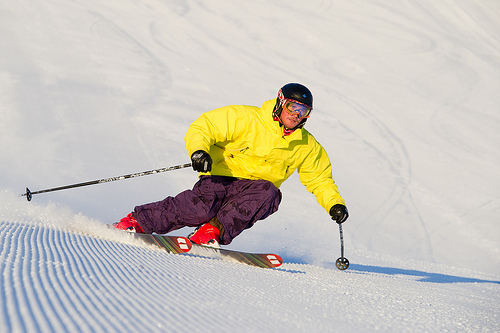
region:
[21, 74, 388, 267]
A man skiing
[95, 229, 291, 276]
A pair of skis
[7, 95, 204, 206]
A ski pole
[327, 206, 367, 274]
A ski pole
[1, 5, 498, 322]
The ground covered in snow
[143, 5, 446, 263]
ski tracks in the snow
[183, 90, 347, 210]
Yellow jacket on the skier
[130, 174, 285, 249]
purple pants on the skier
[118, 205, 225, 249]
red shoes on the skier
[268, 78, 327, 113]
black helmet on the skier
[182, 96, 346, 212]
skier in yellow jacket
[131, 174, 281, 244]
skier in purple pants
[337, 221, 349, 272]
ski pole in left hand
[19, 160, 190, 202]
ski pole in right hand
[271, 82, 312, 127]
skier wearing black helmet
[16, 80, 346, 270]
skier is leaning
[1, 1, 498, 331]
skier is on slope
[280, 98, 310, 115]
goggles are under helmet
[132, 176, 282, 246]
purple pants are loose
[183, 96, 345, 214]
yellow jacket is fastened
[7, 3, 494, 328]
snow covered hill side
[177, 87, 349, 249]
bright yellow ski jacket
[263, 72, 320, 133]
shiny black safety helmet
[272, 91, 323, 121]
red safety ski goggles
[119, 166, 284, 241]
baggy purple ski pants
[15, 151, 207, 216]
outstretched black ski pole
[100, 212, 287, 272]
pair of red and green skis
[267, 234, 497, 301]
shadow of skier in snow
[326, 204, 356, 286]
ski pole in left hand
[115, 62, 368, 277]
downhill skier making a turn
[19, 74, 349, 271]
man skiing in the snow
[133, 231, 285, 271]
silver skiis with red and white tips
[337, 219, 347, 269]
left skii pole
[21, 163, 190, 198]
right skii pole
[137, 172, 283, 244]
purple pants on skiier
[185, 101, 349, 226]
yellow jacket on skiier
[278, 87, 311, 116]
skii goggles on man's head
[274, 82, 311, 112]
skii helmet on man's head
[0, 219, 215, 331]
ripples in the snow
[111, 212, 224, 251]
red boots on skiiers feet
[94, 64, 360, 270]
person wearing a yellow jacket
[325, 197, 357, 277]
pole on left side of hand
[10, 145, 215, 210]
pole on right side of hand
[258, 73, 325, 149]
man wears goggles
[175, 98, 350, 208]
yellow winter coat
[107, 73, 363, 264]
pants of man is purple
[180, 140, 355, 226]
black gloves holding snow poles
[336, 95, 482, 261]
marks of skis on the snow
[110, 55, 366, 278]
man is inclined to the right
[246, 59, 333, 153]
man wears a black helmet